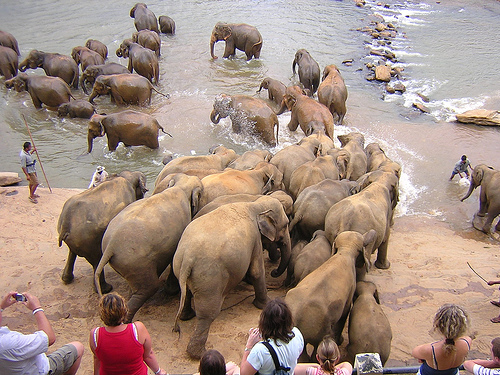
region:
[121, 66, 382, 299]
Elephants going in the water.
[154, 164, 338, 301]
Elephants grouped all together.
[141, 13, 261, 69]
Elephants in the water.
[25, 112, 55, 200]
Man holding a stick near elephants.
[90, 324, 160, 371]
The person is wearing a red shirt.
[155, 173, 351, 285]
The elephants is muddy and dirty.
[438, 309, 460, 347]
The woman has black band in hair.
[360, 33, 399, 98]
Big rocks in the water.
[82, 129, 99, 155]
The elephant trunk in the water.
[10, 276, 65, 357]
A man taking picture of elephants.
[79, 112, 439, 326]
Group of elephants together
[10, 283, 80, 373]
Man taking a picture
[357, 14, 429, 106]
Group of rocks in the water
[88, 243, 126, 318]
Long tail on the elephant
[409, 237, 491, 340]
The hill is dirty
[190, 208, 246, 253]
Dirt on the elephants back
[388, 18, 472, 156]
The water has white caps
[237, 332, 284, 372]
Woman carrying a bag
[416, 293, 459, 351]
Woman with frizzy blonde hair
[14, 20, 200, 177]
Group of elephants in the water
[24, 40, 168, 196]
brown elephants on the water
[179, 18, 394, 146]
brown elephants on the water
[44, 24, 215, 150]
brown elephants on the water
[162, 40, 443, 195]
brown elephants on the water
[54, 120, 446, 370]
elephants walking towards the water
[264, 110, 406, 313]
elephants walking towards the water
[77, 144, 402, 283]
elephants walking towards the water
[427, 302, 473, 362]
Women with blonde curly hair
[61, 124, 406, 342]
Group of elephants walking in the water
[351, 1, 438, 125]
Rocks in the water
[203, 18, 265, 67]
Elephant standing in the water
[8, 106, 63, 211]
Man standing holding a stick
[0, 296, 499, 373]
Crowd watching the elephants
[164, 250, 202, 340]
Tail on elephant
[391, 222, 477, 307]
Sand by the water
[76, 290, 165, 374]
Woman wearing a red shirt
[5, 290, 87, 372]
the man is sitted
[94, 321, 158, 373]
the shirt is red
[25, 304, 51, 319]
the wrist band is white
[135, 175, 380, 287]
the elephants are brown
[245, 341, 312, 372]
the shirt is white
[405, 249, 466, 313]
the sand is brown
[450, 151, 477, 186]
the man is in the water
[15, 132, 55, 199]
the man has a pole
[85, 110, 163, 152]
the elepjhant is wet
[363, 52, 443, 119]
the rocks are in the water